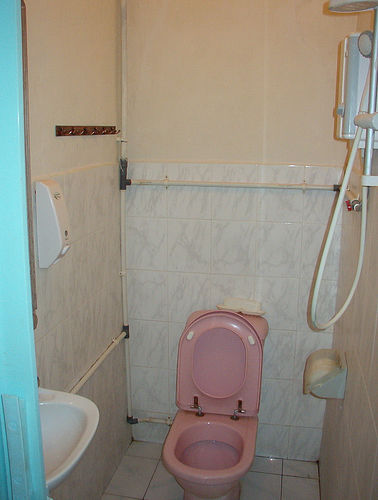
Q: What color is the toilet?
A: Pink.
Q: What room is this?
A: Bathroom.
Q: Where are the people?
A: Not in the bathroom.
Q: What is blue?
A: The door.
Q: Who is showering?
A: No one.